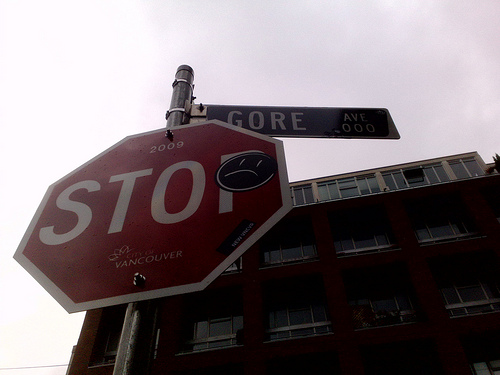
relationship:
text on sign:
[114, 249, 182, 267] [13, 118, 295, 315]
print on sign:
[150, 140, 185, 155] [13, 118, 295, 315]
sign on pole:
[13, 118, 295, 315] [124, 64, 196, 375]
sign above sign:
[207, 104, 401, 140] [13, 118, 295, 315]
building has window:
[65, 150, 500, 374] [327, 205, 402, 257]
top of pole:
[166, 65, 193, 126] [124, 64, 196, 375]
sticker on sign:
[216, 150, 278, 192] [13, 118, 295, 315]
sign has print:
[13, 118, 295, 315] [150, 140, 185, 155]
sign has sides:
[13, 118, 295, 315] [14, 119, 295, 313]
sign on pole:
[207, 104, 401, 140] [124, 64, 196, 375]